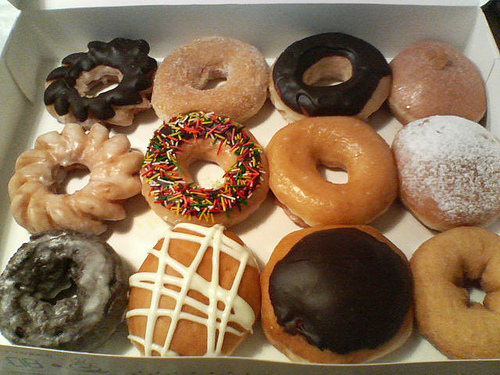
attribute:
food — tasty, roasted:
[46, 56, 400, 263]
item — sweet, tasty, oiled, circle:
[167, 96, 249, 191]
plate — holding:
[157, 5, 301, 44]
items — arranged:
[103, 40, 362, 198]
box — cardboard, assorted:
[42, 12, 498, 109]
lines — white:
[178, 245, 265, 322]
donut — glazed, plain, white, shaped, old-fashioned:
[289, 130, 434, 216]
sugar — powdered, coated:
[384, 115, 494, 234]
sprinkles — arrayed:
[170, 134, 265, 220]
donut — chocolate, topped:
[294, 28, 411, 105]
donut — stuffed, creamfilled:
[401, 44, 485, 114]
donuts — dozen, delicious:
[65, 107, 374, 286]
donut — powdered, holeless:
[412, 118, 477, 204]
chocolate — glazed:
[279, 49, 317, 117]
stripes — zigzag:
[145, 226, 268, 280]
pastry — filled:
[396, 69, 462, 116]